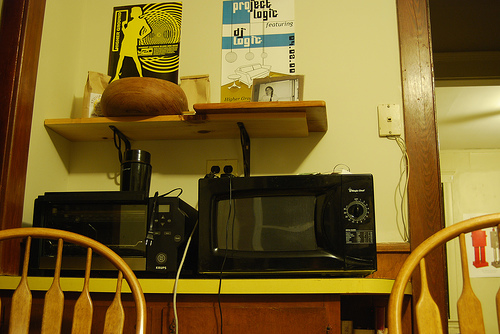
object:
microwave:
[197, 174, 377, 277]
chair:
[0, 227, 148, 334]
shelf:
[44, 111, 310, 142]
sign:
[221, 1, 294, 105]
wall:
[66, 1, 411, 247]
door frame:
[396, 1, 498, 333]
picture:
[107, 1, 182, 87]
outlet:
[206, 163, 236, 178]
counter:
[0, 275, 413, 296]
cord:
[218, 171, 232, 333]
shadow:
[436, 109, 500, 127]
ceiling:
[435, 86, 500, 151]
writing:
[344, 227, 373, 245]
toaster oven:
[32, 189, 198, 276]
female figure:
[110, 6, 153, 82]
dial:
[351, 205, 363, 218]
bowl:
[100, 76, 187, 117]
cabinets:
[0, 293, 340, 333]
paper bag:
[82, 70, 111, 119]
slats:
[10, 236, 126, 333]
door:
[197, 173, 344, 273]